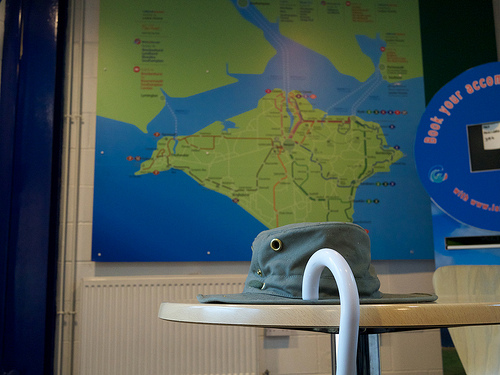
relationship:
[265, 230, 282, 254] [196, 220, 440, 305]
hole on hat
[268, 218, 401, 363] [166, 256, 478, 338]
handle on table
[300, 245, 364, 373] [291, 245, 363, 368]
hook coming off a label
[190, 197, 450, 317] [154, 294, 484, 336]
hat sitting on table top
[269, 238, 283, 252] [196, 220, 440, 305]
hole on side of hat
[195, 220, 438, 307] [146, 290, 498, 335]
hat on table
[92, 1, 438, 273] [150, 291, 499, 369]
map on table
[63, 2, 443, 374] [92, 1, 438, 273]
wall behind map